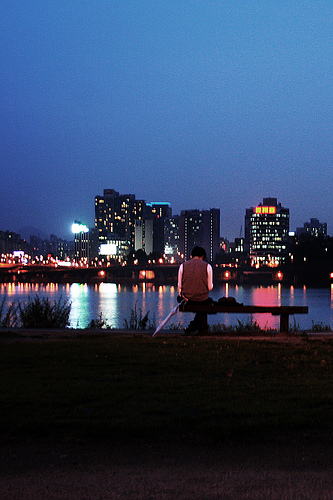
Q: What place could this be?
A: It is a field.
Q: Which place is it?
A: It is a field.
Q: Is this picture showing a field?
A: Yes, it is showing a field.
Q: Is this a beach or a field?
A: It is a field.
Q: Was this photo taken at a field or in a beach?
A: It was taken at a field.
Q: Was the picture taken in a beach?
A: No, the picture was taken in a field.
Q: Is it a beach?
A: No, it is a field.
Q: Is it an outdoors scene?
A: Yes, it is outdoors.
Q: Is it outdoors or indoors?
A: It is outdoors.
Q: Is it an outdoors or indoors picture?
A: It is outdoors.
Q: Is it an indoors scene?
A: No, it is outdoors.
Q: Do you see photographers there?
A: No, there are no photographers.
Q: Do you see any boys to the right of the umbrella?
A: Yes, there is a boy to the right of the umbrella.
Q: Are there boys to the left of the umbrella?
A: No, the boy is to the right of the umbrella.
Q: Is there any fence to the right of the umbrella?
A: No, there is a boy to the right of the umbrella.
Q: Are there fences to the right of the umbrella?
A: No, there is a boy to the right of the umbrella.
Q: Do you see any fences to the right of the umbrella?
A: No, there is a boy to the right of the umbrella.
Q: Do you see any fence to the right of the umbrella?
A: No, there is a boy to the right of the umbrella.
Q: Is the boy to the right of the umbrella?
A: Yes, the boy is to the right of the umbrella.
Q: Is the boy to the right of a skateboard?
A: No, the boy is to the right of the umbrella.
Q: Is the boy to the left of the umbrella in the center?
A: No, the boy is to the right of the umbrella.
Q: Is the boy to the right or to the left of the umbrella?
A: The boy is to the right of the umbrella.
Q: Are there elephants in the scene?
A: No, there are no elephants.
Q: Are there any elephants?
A: No, there are no elephants.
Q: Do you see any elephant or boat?
A: No, there are no elephants or boats.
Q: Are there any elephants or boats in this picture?
A: No, there are no elephants or boats.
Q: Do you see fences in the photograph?
A: No, there are no fences.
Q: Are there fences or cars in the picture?
A: No, there are no fences or cars.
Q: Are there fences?
A: No, there are no fences.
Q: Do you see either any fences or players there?
A: No, there are no fences or players.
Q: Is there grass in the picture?
A: Yes, there is grass.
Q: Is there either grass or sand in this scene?
A: Yes, there is grass.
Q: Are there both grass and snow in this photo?
A: No, there is grass but no snow.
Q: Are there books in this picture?
A: No, there are no books.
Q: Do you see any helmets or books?
A: No, there are no books or helmets.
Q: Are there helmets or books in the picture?
A: No, there are no books or helmets.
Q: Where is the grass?
A: The grass is on the field.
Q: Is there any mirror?
A: No, there are no mirrors.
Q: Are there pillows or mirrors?
A: No, there are no mirrors or pillows.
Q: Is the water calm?
A: Yes, the water is calm.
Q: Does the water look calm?
A: Yes, the water is calm.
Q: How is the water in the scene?
A: The water is calm.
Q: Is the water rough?
A: No, the water is calm.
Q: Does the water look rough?
A: No, the water is calm.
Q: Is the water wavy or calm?
A: The water is calm.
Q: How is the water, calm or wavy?
A: The water is calm.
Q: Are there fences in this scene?
A: No, there are no fences.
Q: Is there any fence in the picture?
A: No, there are no fences.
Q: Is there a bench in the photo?
A: Yes, there is a bench.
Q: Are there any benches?
A: Yes, there is a bench.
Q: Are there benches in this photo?
A: Yes, there is a bench.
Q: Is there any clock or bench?
A: Yes, there is a bench.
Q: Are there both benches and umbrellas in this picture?
A: Yes, there are both a bench and an umbrella.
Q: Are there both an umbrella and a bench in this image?
A: Yes, there are both a bench and an umbrella.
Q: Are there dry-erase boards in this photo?
A: No, there are no dry-erase boards.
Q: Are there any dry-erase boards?
A: No, there are no dry-erase boards.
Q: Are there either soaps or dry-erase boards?
A: No, there are no dry-erase boards or soaps.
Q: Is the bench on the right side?
A: Yes, the bench is on the right of the image.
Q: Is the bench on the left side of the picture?
A: No, the bench is on the right of the image.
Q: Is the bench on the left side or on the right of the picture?
A: The bench is on the right of the image.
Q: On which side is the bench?
A: The bench is on the right of the image.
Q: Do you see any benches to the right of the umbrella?
A: Yes, there is a bench to the right of the umbrella.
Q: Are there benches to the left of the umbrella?
A: No, the bench is to the right of the umbrella.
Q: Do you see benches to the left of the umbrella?
A: No, the bench is to the right of the umbrella.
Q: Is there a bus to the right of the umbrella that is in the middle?
A: No, there is a bench to the right of the umbrella.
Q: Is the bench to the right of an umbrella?
A: Yes, the bench is to the right of an umbrella.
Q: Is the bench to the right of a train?
A: No, the bench is to the right of an umbrella.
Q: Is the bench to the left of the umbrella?
A: No, the bench is to the right of the umbrella.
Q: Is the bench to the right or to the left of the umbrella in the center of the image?
A: The bench is to the right of the umbrella.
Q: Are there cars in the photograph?
A: No, there are no cars.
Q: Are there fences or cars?
A: No, there are no cars or fences.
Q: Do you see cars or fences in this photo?
A: No, there are no cars or fences.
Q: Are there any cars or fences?
A: No, there are no cars or fences.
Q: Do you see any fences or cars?
A: No, there are no cars or fences.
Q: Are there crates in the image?
A: No, there are no crates.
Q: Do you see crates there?
A: No, there are no crates.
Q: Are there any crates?
A: No, there are no crates.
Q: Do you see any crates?
A: No, there are no crates.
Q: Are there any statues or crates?
A: No, there are no crates or statues.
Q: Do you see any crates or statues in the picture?
A: No, there are no crates or statues.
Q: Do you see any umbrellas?
A: Yes, there is an umbrella.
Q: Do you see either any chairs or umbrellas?
A: Yes, there is an umbrella.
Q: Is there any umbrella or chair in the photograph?
A: Yes, there is an umbrella.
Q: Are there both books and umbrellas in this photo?
A: No, there is an umbrella but no books.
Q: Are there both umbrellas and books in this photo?
A: No, there is an umbrella but no books.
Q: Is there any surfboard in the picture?
A: No, there are no surfboards.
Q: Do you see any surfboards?
A: No, there are no surfboards.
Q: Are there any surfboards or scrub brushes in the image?
A: No, there are no surfboards or scrub brushes.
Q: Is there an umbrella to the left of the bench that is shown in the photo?
A: Yes, there is an umbrella to the left of the bench.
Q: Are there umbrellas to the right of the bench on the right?
A: No, the umbrella is to the left of the bench.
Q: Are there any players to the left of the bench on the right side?
A: No, there is an umbrella to the left of the bench.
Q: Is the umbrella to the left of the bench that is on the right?
A: Yes, the umbrella is to the left of the bench.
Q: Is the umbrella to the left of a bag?
A: No, the umbrella is to the left of the bench.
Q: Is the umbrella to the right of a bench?
A: No, the umbrella is to the left of a bench.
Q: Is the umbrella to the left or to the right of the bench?
A: The umbrella is to the left of the bench.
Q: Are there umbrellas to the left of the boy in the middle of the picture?
A: Yes, there is an umbrella to the left of the boy.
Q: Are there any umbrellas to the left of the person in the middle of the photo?
A: Yes, there is an umbrella to the left of the boy.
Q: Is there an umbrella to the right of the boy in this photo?
A: No, the umbrella is to the left of the boy.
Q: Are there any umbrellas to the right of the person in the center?
A: No, the umbrella is to the left of the boy.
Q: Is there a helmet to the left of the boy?
A: No, there is an umbrella to the left of the boy.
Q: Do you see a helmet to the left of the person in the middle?
A: No, there is an umbrella to the left of the boy.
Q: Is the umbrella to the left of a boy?
A: Yes, the umbrella is to the left of a boy.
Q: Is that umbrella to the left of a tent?
A: No, the umbrella is to the left of a boy.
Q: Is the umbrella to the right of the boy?
A: No, the umbrella is to the left of the boy.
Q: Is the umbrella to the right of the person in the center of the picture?
A: No, the umbrella is to the left of the boy.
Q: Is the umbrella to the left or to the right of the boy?
A: The umbrella is to the left of the boy.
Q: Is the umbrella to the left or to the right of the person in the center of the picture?
A: The umbrella is to the left of the boy.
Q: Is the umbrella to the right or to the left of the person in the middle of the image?
A: The umbrella is to the left of the boy.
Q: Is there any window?
A: Yes, there are windows.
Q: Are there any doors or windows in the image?
A: Yes, there are windows.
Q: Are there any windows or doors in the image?
A: Yes, there are windows.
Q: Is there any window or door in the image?
A: Yes, there are windows.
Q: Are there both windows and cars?
A: No, there are windows but no cars.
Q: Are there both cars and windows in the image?
A: No, there are windows but no cars.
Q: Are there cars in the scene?
A: No, there are no cars.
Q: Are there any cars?
A: No, there are no cars.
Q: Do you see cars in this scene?
A: No, there are no cars.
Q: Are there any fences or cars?
A: No, there are no cars or fences.